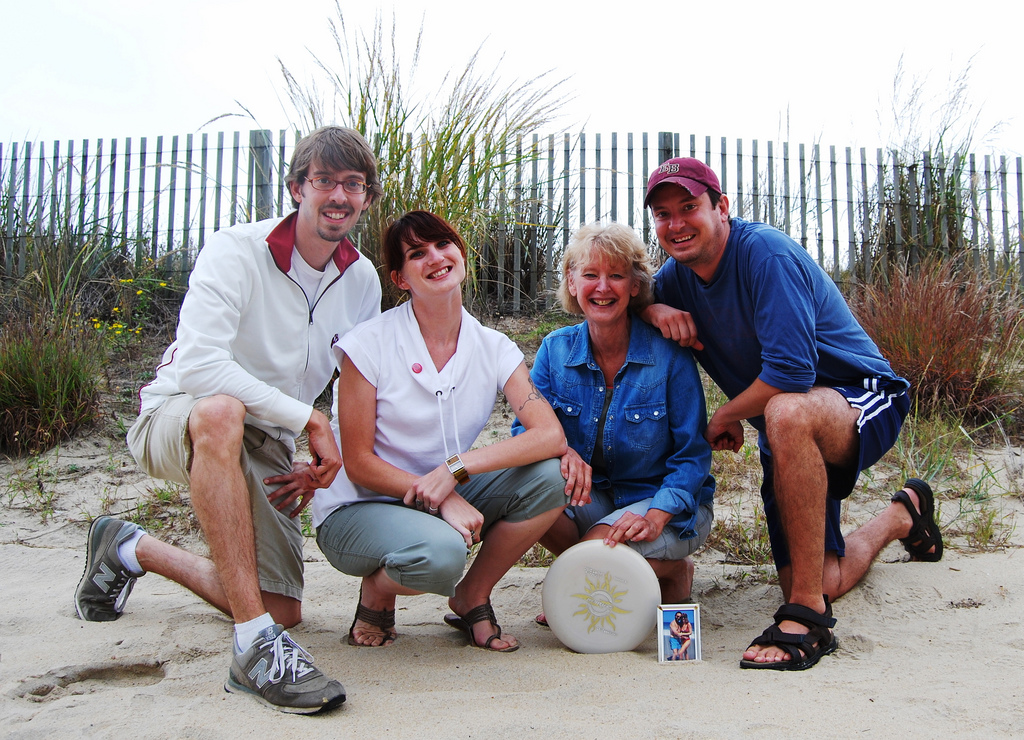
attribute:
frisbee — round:
[528, 534, 673, 662]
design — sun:
[564, 562, 631, 638]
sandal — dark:
[735, 590, 837, 670]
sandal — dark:
[880, 467, 943, 565]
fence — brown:
[222, 108, 935, 359]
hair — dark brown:
[293, 117, 382, 191]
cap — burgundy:
[661, 603, 726, 666]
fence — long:
[65, 122, 686, 278]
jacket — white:
[143, 211, 385, 451]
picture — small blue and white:
[643, 572, 758, 683]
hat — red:
[622, 137, 724, 231]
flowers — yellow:
[26, 204, 135, 408]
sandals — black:
[728, 587, 873, 717]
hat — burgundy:
[635, 140, 709, 214]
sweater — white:
[326, 286, 549, 507]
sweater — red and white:
[136, 204, 363, 470]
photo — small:
[658, 605, 708, 666]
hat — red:
[641, 150, 721, 203]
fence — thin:
[553, 134, 646, 199]